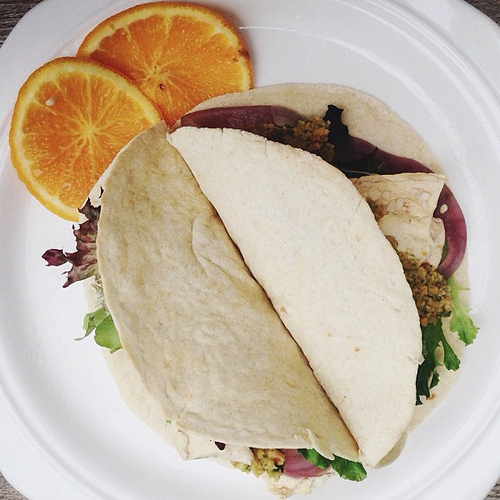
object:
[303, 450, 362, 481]
lettuce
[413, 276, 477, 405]
lettuce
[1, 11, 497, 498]
plate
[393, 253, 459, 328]
meat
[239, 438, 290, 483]
meat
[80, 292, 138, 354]
lettuce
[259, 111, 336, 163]
meat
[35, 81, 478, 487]
tacos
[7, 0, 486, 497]
food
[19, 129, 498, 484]
plate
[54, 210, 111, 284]
lettuce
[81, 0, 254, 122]
orange slice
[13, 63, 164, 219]
orange slice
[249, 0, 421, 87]
plate